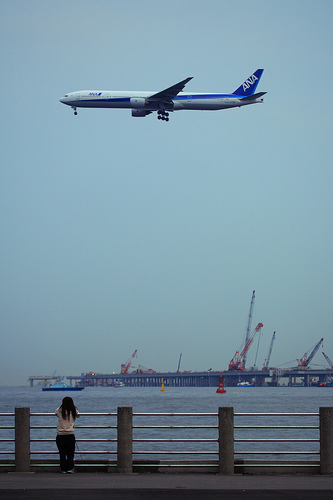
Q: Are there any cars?
A: No, there are no cars.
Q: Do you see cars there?
A: No, there are no cars.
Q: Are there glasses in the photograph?
A: No, there are no glasses.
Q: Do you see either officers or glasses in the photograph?
A: No, there are no glasses or officers.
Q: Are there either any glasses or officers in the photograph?
A: No, there are no glasses or officers.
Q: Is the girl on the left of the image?
A: Yes, the girl is on the left of the image.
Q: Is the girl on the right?
A: No, the girl is on the left of the image.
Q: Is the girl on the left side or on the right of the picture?
A: The girl is on the left of the image.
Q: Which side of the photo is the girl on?
A: The girl is on the left of the image.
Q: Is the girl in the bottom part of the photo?
A: Yes, the girl is in the bottom of the image.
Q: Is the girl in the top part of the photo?
A: No, the girl is in the bottom of the image.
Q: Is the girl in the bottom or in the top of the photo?
A: The girl is in the bottom of the image.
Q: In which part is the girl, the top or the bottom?
A: The girl is in the bottom of the image.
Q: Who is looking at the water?
A: The girl is looking at the water.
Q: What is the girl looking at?
A: The girl is looking at the water.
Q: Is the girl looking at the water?
A: Yes, the girl is looking at the water.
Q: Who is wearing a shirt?
A: The girl is wearing a shirt.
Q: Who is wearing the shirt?
A: The girl is wearing a shirt.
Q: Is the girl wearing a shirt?
A: Yes, the girl is wearing a shirt.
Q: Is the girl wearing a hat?
A: No, the girl is wearing a shirt.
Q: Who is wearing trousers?
A: The girl is wearing trousers.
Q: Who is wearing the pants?
A: The girl is wearing trousers.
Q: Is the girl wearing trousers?
A: Yes, the girl is wearing trousers.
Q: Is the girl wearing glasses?
A: No, the girl is wearing trousers.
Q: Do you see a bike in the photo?
A: No, there are no bikes.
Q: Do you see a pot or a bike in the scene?
A: No, there are no bikes or pots.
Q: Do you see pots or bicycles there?
A: No, there are no bicycles or pots.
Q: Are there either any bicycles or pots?
A: No, there are no bicycles or pots.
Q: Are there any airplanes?
A: Yes, there is an airplane.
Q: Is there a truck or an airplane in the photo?
A: Yes, there is an airplane.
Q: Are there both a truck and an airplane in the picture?
A: No, there is an airplane but no trucks.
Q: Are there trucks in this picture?
A: No, there are no trucks.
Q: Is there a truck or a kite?
A: No, there are no trucks or kites.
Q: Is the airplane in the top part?
A: Yes, the airplane is in the top of the image.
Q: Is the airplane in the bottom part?
A: No, the airplane is in the top of the image.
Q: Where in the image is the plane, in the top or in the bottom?
A: The plane is in the top of the image.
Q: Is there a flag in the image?
A: No, there are no flags.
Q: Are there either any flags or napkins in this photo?
A: No, there are no flags or napkins.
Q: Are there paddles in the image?
A: No, there are no paddles.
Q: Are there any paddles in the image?
A: No, there are no paddles.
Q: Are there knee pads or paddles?
A: No, there are no paddles or knee pads.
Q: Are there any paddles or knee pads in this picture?
A: No, there are no paddles or knee pads.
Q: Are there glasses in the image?
A: No, there are no glasses.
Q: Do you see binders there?
A: No, there are no binders.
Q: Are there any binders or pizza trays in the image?
A: No, there are no binders or pizza trays.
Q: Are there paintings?
A: No, there are no paintings.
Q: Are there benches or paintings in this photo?
A: No, there are no paintings or benches.